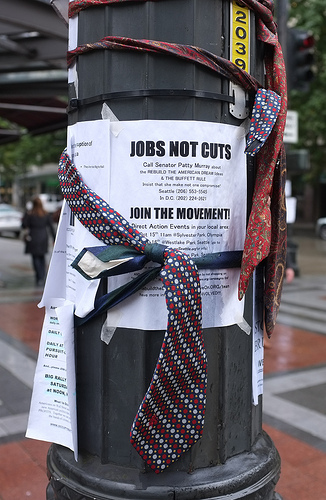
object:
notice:
[105, 118, 247, 328]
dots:
[171, 301, 201, 356]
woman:
[21, 195, 56, 288]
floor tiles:
[275, 338, 312, 367]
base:
[46, 442, 281, 499]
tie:
[237, 0, 288, 303]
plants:
[0, 129, 56, 175]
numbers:
[234, 8, 248, 74]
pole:
[43, 0, 279, 497]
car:
[0, 201, 24, 239]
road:
[6, 251, 45, 339]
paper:
[109, 117, 248, 330]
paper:
[23, 296, 78, 459]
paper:
[39, 122, 112, 308]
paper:
[252, 262, 264, 401]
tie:
[57, 151, 209, 471]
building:
[0, 0, 69, 138]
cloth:
[71, 242, 243, 326]